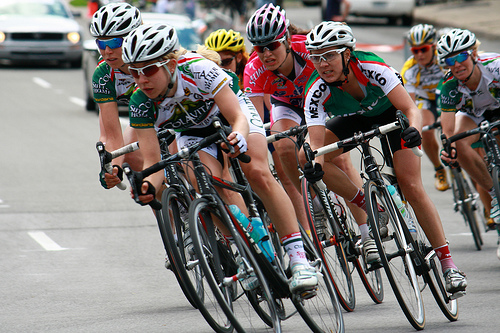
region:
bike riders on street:
[88, 0, 498, 332]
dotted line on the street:
[3, 71, 130, 255]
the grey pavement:
[1, 5, 499, 332]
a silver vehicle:
[1, 3, 84, 63]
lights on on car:
[2, 29, 79, 42]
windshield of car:
[2, 2, 69, 15]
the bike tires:
[150, 153, 499, 332]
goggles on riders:
[93, 36, 471, 78]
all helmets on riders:
[88, 1, 480, 63]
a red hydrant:
[85, 2, 98, 13]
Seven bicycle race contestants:
[81, 0, 498, 330]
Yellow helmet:
[203, 23, 242, 56]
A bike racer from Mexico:
[296, 25, 472, 327]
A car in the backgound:
[3, 8, 82, 70]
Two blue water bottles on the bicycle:
[226, 202, 277, 262]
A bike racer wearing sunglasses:
[128, 63, 172, 75]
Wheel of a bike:
[362, 181, 428, 328]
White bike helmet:
[121, 23, 178, 61]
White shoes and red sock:
[432, 241, 463, 292]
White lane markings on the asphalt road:
[23, 65, 141, 128]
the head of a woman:
[100, 29, 224, 127]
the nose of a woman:
[126, 70, 156, 100]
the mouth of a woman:
[132, 72, 163, 103]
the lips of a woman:
[132, 80, 163, 117]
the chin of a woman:
[126, 66, 181, 115]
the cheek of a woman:
[146, 58, 176, 102]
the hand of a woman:
[213, 111, 270, 175]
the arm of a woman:
[183, 64, 264, 165]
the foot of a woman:
[260, 220, 328, 296]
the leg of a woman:
[364, 118, 460, 284]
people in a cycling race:
[16, 17, 486, 308]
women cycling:
[18, 2, 481, 317]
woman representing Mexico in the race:
[290, 25, 476, 315]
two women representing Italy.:
[55, 5, 330, 291]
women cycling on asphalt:
[1, 63, 487, 321]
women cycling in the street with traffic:
[11, 67, 482, 319]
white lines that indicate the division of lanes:
[25, 68, 166, 155]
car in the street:
[0, 0, 85, 70]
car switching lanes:
[80, 6, 195, 106]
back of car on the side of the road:
[311, 1, 426, 23]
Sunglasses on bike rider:
[119, 64, 172, 76]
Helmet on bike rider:
[305, 18, 355, 50]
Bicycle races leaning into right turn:
[86, 4, 495, 331]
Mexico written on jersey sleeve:
[302, 80, 326, 122]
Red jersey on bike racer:
[236, 35, 319, 109]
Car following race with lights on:
[1, 0, 79, 72]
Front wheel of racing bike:
[361, 175, 426, 329]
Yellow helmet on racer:
[203, 28, 243, 54]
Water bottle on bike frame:
[227, 200, 274, 262]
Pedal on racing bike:
[295, 286, 317, 300]